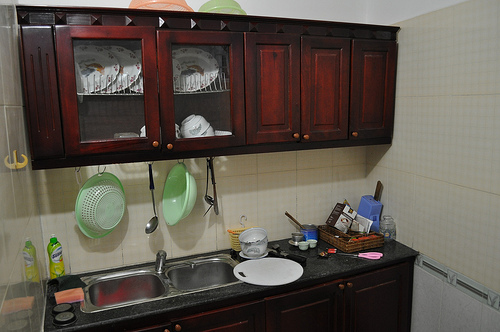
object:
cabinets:
[16, 5, 401, 171]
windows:
[52, 25, 245, 149]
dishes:
[73, 38, 120, 94]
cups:
[181, 114, 211, 138]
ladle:
[145, 164, 159, 234]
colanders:
[73, 172, 125, 239]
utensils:
[161, 162, 199, 227]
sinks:
[88, 271, 168, 307]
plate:
[233, 257, 304, 286]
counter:
[43, 237, 420, 331]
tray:
[318, 225, 385, 254]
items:
[324, 201, 357, 233]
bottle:
[47, 234, 66, 280]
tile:
[418, 253, 500, 311]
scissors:
[337, 251, 383, 259]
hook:
[13, 149, 28, 170]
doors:
[50, 25, 162, 152]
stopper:
[51, 312, 79, 325]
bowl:
[128, 0, 194, 13]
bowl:
[199, 0, 247, 15]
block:
[356, 195, 384, 233]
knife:
[373, 180, 384, 202]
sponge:
[54, 287, 85, 305]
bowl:
[238, 227, 269, 257]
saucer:
[239, 251, 268, 260]